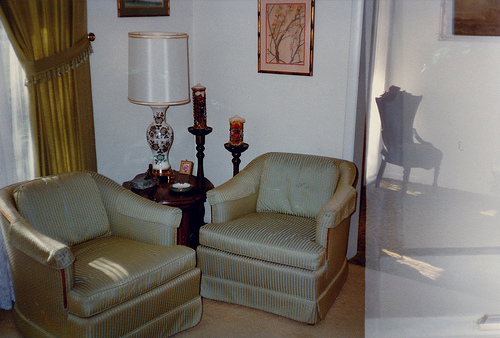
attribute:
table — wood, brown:
[125, 163, 214, 252]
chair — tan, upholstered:
[0, 140, 202, 337]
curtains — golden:
[1, 0, 98, 310]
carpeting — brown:
[1, 261, 496, 336]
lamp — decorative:
[124, 24, 192, 204]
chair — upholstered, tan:
[202, 151, 356, 316]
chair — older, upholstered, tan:
[0, 168, 201, 328]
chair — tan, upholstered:
[192, 142, 370, 334]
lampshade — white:
[105, 17, 225, 177]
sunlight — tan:
[93, 256, 128, 281]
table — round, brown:
[117, 166, 216, 248]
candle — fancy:
[191, 79, 208, 128]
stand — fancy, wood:
[188, 125, 213, 182]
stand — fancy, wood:
[221, 140, 249, 177]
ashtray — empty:
[166, 178, 197, 196]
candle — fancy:
[227, 112, 244, 145]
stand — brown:
[224, 142, 248, 175]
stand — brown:
[188, 126, 213, 177]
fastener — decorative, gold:
[84, 29, 94, 41]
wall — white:
[83, 1, 356, 261]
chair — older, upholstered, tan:
[191, 146, 363, 326]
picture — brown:
[268, 0, 335, 80]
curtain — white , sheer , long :
[2, 7, 107, 180]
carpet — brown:
[171, 263, 369, 336]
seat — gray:
[197, 148, 359, 323]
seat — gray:
[0, 170, 202, 335]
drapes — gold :
[8, 2, 97, 185]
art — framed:
[114, 0, 174, 20]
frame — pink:
[256, 0, 315, 77]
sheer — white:
[0, 24, 38, 310]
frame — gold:
[255, 0, 320, 81]